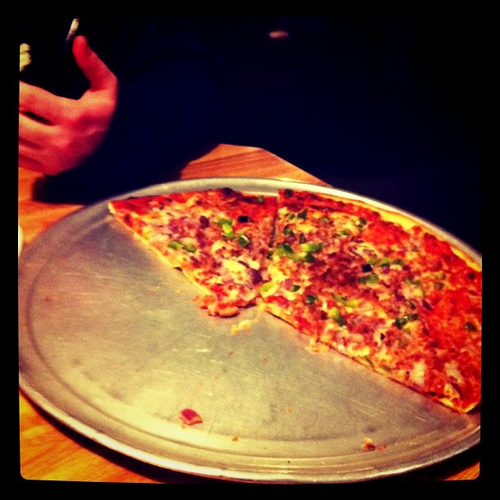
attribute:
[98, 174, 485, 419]
pizza — melted, eaten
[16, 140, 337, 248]
table — brown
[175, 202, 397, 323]
pizza — half-eaten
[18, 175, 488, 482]
pizza pan — shiny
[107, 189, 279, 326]
pizza — charred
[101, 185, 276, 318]
pizza slice — moved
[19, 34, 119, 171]
hand — white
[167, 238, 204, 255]
pepper — diced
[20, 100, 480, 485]
pizza pan — metal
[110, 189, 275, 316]
pizza — sliced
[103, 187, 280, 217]
pizza crust — thin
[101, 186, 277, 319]
slice — pizza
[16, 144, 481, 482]
tabletop — brown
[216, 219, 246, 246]
topping — green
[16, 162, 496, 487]
pizza — baked, resting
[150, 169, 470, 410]
pizza pan — circular